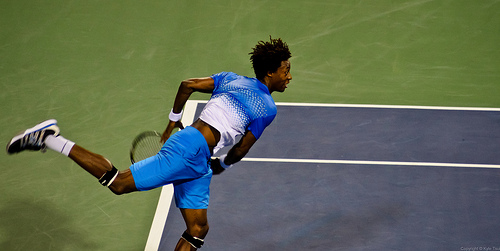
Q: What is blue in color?
A: Shorts.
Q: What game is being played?
A: Tennis.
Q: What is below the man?
A: Tennis court.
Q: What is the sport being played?
A: Tennis.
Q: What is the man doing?
A: Playing tennis.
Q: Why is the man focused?
A: He is playing.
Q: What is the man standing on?
A: A tennis court.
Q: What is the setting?
A: A tennis court.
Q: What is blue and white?
A: His shirt.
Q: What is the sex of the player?
A: Male.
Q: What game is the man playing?
A: Tennis.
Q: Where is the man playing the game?
A: Tennis court.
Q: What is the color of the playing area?
A: Gray.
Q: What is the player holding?
A: Tennis racket.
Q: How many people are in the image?
A: One.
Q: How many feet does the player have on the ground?
A: One.